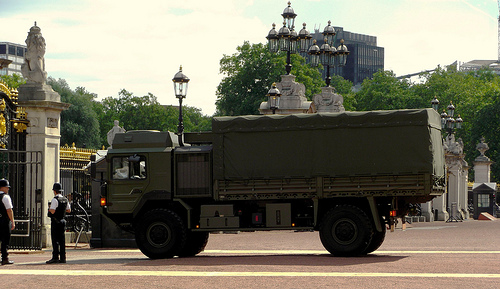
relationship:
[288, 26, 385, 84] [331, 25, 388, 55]
building has top